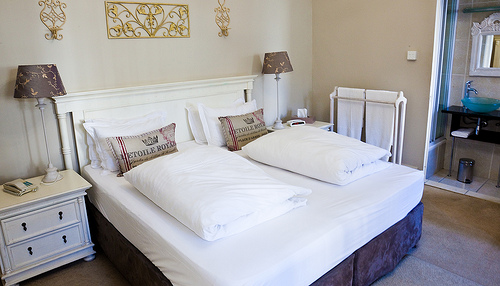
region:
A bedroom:
[4, 3, 432, 283]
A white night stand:
[2, 168, 96, 284]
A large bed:
[54, 72, 439, 284]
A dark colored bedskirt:
[77, 190, 430, 283]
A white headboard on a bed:
[30, 72, 287, 182]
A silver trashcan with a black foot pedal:
[453, 153, 477, 187]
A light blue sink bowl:
[456, 92, 498, 117]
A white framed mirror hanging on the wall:
[467, 13, 499, 83]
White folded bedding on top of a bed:
[127, 116, 397, 238]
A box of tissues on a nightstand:
[292, 104, 334, 134]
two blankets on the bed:
[140, 143, 391, 190]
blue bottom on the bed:
[352, 242, 436, 284]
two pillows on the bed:
[106, 115, 267, 159]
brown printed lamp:
[18, 71, 70, 103]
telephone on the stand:
[0, 180, 37, 196]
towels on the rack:
[331, 89, 411, 143]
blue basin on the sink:
[461, 100, 493, 112]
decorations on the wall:
[33, 5, 239, 39]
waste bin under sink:
[458, 157, 490, 196]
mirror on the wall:
[480, 29, 498, 72]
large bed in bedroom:
[40, 69, 434, 284]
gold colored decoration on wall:
[97, 2, 198, 44]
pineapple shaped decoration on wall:
[32, 0, 75, 44]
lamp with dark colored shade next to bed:
[255, 42, 300, 133]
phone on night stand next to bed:
[2, 174, 39, 200]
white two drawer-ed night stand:
[2, 162, 102, 283]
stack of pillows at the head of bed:
[76, 108, 193, 173]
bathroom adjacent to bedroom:
[417, 2, 497, 212]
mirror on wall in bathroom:
[465, 9, 498, 82]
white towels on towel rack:
[317, 79, 412, 174]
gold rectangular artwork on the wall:
[101, 0, 191, 41]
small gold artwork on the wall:
[36, 1, 69, 41]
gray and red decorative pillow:
[106, 122, 178, 174]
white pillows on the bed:
[78, 105, 168, 172]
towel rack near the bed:
[326, 83, 407, 167]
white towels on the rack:
[336, 84, 398, 151]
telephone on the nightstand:
[2, 175, 41, 197]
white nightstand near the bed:
[0, 166, 98, 284]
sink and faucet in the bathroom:
[459, 75, 499, 113]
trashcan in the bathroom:
[454, 153, 479, 185]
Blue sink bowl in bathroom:
[461, 90, 498, 117]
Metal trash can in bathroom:
[457, 156, 475, 184]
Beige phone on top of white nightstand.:
[0, 175, 37, 195]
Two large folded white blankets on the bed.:
[122, 121, 393, 241]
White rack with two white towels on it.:
[322, 85, 412, 165]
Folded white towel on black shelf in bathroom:
[450, 125, 470, 140]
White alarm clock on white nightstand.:
[282, 113, 303, 128]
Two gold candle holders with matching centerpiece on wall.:
[37, 0, 235, 38]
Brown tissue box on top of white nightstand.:
[291, 105, 313, 122]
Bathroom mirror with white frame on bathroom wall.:
[467, 13, 498, 79]